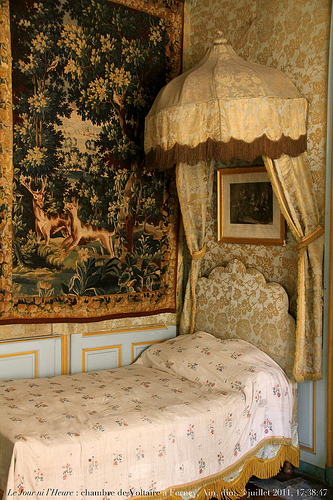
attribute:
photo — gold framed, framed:
[214, 164, 288, 246]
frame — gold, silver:
[212, 164, 287, 249]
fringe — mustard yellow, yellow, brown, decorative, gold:
[189, 447, 303, 499]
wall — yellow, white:
[71, 319, 177, 377]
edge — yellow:
[82, 324, 170, 338]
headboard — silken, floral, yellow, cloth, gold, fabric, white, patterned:
[182, 256, 301, 383]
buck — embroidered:
[13, 171, 77, 253]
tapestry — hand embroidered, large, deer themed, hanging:
[3, 1, 185, 325]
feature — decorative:
[139, 27, 310, 174]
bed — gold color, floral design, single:
[0, 256, 304, 499]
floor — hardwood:
[243, 467, 332, 500]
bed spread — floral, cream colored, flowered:
[2, 330, 296, 499]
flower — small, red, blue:
[214, 362, 226, 375]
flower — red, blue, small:
[39, 430, 53, 442]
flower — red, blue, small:
[132, 443, 146, 462]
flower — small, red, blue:
[80, 391, 94, 402]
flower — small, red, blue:
[223, 412, 236, 431]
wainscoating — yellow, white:
[2, 321, 178, 380]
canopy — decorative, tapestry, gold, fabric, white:
[142, 24, 326, 386]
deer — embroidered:
[58, 195, 120, 263]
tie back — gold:
[293, 224, 325, 253]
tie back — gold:
[191, 238, 209, 260]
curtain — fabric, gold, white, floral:
[256, 138, 325, 383]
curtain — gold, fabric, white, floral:
[169, 145, 214, 335]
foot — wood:
[0, 425, 30, 500]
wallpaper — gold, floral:
[191, 2, 329, 327]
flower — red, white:
[76, 247, 91, 264]